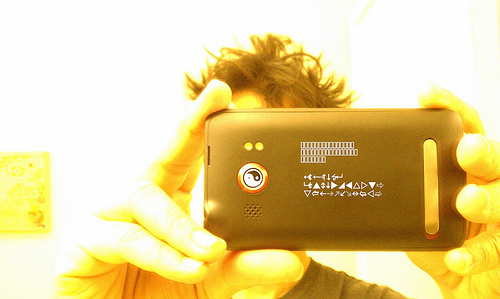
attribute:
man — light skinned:
[61, 35, 499, 297]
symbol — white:
[307, 181, 322, 194]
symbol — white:
[306, 176, 326, 201]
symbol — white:
[324, 185, 335, 197]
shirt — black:
[297, 259, 374, 297]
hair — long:
[250, 36, 298, 81]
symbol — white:
[334, 186, 349, 201]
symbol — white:
[311, 189, 319, 198]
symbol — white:
[365, 174, 382, 190]